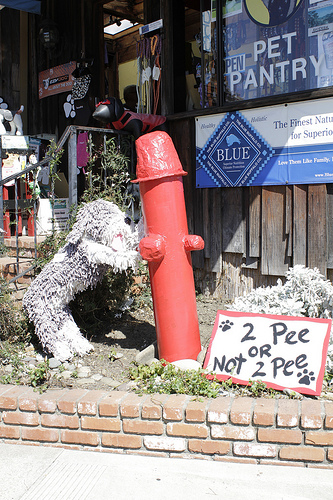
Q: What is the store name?
A: Pet pantry.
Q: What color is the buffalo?
A: Blue.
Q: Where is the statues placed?
A: Flower bed.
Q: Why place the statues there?
A: Funny.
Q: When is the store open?
A: Now.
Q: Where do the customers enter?
A: Door.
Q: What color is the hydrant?
A: Red.